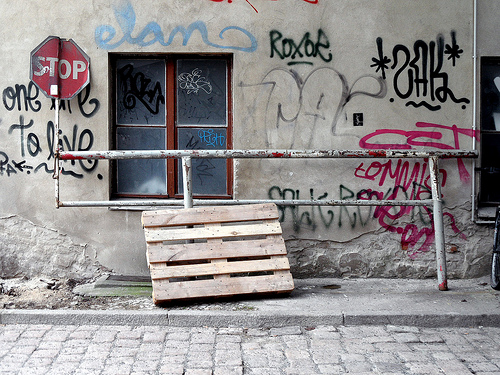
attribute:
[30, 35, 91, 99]
sign — red, white, crumpled, destroyed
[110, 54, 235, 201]
window — brown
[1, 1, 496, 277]
wall — gray, cement, chipped, concrete, dirty, stone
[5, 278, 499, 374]
floor — gray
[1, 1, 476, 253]
letters — black, red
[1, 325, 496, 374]
street — white, brick, bricked, stone, cobblestone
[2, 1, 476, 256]
words — blue, red, black, paint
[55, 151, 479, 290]
rail — white, metal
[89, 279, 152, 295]
slab — green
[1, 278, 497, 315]
sidewalk — gray, white, dirty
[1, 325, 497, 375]
bricks — dry, dirty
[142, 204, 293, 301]
pallet — wooden, brown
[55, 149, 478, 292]
gate — dismantled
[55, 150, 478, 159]
bar — metal